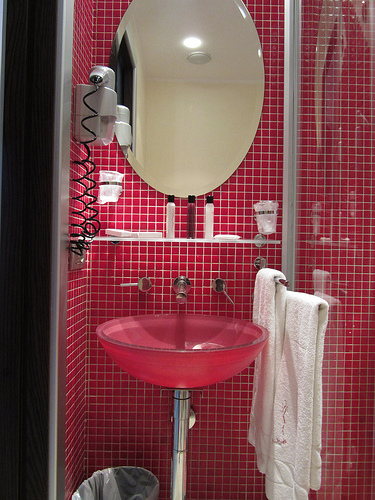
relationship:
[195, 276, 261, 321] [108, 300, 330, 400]
knob on sink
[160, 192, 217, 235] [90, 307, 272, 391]
bottles above sink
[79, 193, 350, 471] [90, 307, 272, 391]
tile behind sink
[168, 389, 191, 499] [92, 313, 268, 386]
pipe to sink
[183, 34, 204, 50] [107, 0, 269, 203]
light reflection on mirror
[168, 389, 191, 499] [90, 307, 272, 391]
pipe of sink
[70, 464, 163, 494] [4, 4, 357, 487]
can in bathroom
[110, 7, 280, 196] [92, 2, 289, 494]
mirror on wall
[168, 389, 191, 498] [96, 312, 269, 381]
pipe beneath sink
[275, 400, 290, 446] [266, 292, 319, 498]
design in towel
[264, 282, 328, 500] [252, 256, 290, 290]
towels on rack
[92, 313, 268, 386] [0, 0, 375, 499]
sink in a restroom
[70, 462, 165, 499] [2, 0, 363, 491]
can in a restroom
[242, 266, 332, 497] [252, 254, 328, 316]
towels on racks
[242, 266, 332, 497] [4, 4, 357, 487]
towels in a bathroom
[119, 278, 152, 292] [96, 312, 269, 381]
knob to a sink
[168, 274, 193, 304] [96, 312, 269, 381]
faucet of a sink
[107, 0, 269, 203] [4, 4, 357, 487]
mirror in a bathroom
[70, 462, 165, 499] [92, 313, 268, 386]
can below sink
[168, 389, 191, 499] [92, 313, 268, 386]
pipe below sink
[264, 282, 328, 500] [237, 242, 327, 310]
towels on rack